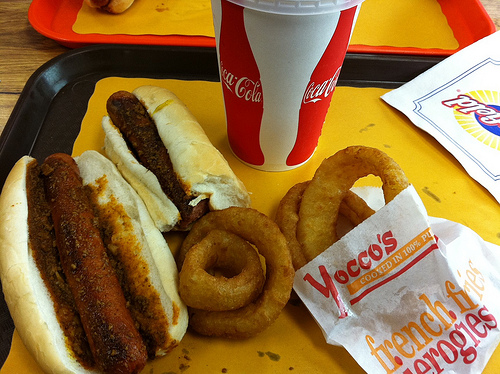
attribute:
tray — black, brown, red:
[8, 40, 498, 353]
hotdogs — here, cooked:
[11, 77, 208, 367]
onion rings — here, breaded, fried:
[170, 202, 299, 338]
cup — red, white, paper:
[199, 3, 366, 171]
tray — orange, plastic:
[20, 2, 494, 60]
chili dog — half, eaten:
[96, 74, 249, 216]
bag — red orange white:
[307, 185, 490, 369]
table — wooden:
[4, 26, 30, 81]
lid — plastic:
[217, 0, 367, 19]